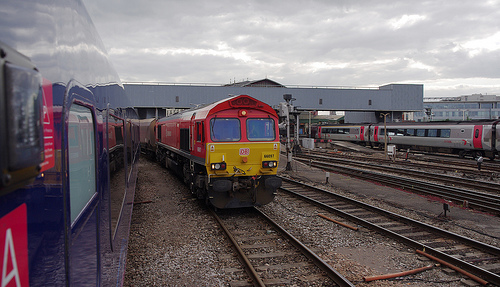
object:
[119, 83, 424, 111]
building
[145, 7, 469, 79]
clouds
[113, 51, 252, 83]
cloud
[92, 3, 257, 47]
cloud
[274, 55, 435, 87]
cloud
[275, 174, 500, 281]
tracks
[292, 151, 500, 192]
tracks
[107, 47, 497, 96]
cloud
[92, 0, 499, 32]
cloud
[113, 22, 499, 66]
cloud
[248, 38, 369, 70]
clouds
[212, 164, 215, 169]
light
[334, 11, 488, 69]
clouds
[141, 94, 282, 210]
train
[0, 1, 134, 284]
train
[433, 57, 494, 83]
clouds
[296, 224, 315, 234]
rocks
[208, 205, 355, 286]
track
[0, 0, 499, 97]
blue sky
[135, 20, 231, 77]
white clouds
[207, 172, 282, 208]
bumpers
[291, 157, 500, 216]
tracks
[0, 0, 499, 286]
station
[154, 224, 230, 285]
stones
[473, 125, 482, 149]
door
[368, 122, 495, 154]
car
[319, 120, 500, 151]
train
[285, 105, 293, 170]
pole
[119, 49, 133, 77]
clouds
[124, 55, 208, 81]
clouds